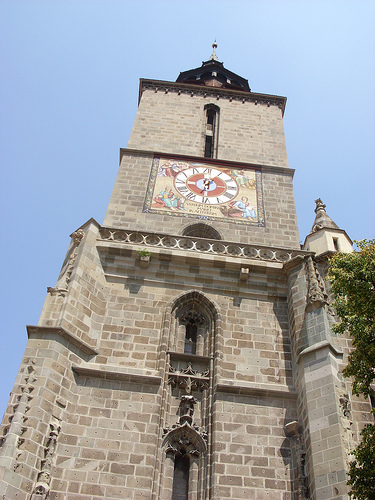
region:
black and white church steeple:
[168, 28, 256, 97]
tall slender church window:
[194, 95, 229, 170]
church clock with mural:
[137, 147, 276, 232]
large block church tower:
[2, 31, 374, 498]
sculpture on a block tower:
[36, 212, 98, 303]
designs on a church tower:
[133, 281, 227, 498]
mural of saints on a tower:
[136, 145, 277, 236]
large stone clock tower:
[3, 25, 373, 496]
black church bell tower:
[159, 30, 264, 98]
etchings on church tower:
[1, 350, 43, 474]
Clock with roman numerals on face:
[170, 158, 245, 207]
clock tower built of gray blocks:
[78, 48, 319, 308]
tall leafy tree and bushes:
[333, 169, 372, 497]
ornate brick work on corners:
[1, 361, 47, 498]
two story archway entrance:
[166, 288, 221, 498]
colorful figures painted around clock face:
[149, 152, 261, 229]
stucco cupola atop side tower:
[300, 195, 357, 254]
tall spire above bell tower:
[189, 38, 243, 93]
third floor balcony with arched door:
[113, 213, 296, 262]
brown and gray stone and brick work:
[67, 392, 152, 498]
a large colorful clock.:
[146, 159, 269, 220]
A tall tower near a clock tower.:
[298, 197, 361, 260]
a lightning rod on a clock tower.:
[198, 31, 233, 63]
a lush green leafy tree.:
[303, 239, 372, 497]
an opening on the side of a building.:
[195, 103, 222, 161]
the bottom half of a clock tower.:
[2, 217, 373, 498]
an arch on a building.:
[193, 94, 231, 162]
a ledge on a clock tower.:
[55, 219, 323, 278]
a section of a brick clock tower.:
[101, 279, 168, 364]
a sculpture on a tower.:
[165, 368, 203, 434]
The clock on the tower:
[173, 162, 237, 207]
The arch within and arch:
[154, 419, 211, 498]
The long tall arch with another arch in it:
[144, 285, 224, 498]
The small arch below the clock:
[174, 216, 222, 241]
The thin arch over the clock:
[200, 100, 221, 160]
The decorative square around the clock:
[141, 154, 269, 229]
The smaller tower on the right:
[299, 191, 359, 282]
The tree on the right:
[321, 232, 374, 498]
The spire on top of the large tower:
[208, 34, 221, 62]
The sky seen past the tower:
[1, 0, 373, 426]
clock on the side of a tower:
[148, 148, 277, 224]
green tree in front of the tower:
[317, 245, 374, 497]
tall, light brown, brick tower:
[4, 24, 369, 498]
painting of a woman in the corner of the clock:
[223, 195, 258, 218]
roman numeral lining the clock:
[202, 166, 241, 199]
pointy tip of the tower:
[206, 32, 224, 55]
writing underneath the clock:
[184, 204, 219, 217]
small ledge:
[75, 357, 160, 380]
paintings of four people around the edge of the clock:
[137, 149, 277, 230]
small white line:
[187, 177, 196, 187]